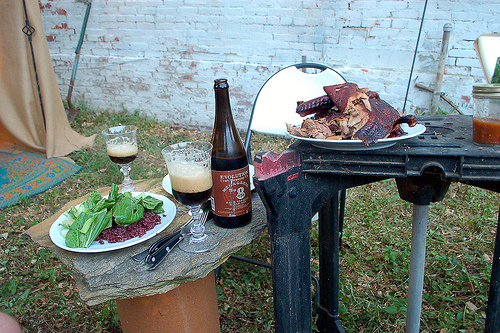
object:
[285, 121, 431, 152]
plate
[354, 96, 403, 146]
meat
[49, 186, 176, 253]
plate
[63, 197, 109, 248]
vegetables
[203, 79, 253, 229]
bottle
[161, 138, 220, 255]
glass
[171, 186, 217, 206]
beverage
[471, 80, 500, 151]
jar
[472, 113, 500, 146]
liquid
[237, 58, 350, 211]
chair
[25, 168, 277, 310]
table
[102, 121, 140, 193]
glass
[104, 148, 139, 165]
beer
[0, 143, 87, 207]
carpet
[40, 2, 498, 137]
wall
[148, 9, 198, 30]
bricks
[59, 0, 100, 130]
shovel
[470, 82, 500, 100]
lid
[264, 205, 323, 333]
leg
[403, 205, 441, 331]
leg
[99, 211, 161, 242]
beans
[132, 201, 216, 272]
fork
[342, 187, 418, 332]
grass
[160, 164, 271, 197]
dish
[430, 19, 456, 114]
pole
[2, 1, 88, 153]
cloth